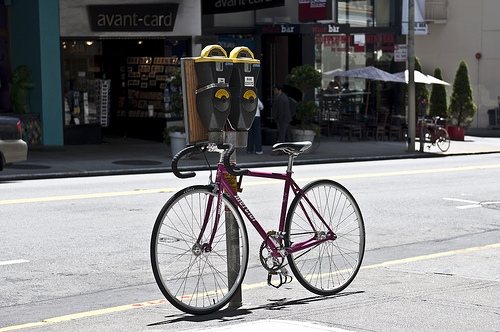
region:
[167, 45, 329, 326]
red bike near parking meter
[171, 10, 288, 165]
black and yellow parking meter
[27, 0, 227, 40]
black sign for avant cafe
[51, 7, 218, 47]
black sign with white lettering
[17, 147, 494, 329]
street with yellow lines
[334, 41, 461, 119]
white umbrellas in photograph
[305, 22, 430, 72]
red lettering on store front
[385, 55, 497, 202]
trees in photograph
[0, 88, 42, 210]
back end of vehicle in photo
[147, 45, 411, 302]
red bike tied to parking meter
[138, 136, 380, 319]
a purple bicycle on the sidewalk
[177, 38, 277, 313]
two parking meters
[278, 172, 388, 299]
a bicycle tire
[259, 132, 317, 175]
black bicycle seat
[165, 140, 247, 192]
black bicycle handle bars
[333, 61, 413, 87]
a large umbrella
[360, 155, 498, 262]
a paved road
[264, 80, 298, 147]
a person standing on the sidewalk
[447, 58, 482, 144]
a tree in a planter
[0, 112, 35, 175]
the bumper of a vehicle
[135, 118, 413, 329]
a red bike parked near a parking meter.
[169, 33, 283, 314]
two yellow parking meters.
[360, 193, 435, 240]
section of a public road.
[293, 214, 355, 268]
spokes within a bike wheel.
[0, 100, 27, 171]
back end of a motor vehicle.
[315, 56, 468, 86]
umbrellas covering seating area.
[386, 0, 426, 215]
large pole on the side of a street.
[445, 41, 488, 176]
a large pine tree near the side of a building.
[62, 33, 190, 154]
store front with sliding door.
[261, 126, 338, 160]
bike seat on the back of a bike.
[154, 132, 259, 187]
a bicycle with a curved handlebar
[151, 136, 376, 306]
a parked pink bicycle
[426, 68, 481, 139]
potted trees outside a bar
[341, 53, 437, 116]
white parasols on a bar's terrace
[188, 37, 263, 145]
two black and yellow parking meters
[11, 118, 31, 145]
the red taillight of a car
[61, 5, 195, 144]
the shop window of a card store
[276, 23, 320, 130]
the entrance to a bar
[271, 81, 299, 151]
a man wearing a blue suit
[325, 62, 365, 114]
a man sitting underneath a parasol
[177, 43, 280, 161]
A double parking meter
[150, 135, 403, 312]
A pink bike leaning against a parking meter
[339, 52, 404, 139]
An umbrella over a table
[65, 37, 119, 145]
A store window display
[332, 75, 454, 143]
Tables outside of a bar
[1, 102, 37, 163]
The tail end of a car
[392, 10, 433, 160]
The post of a street light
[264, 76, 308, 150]
A man wearing a suit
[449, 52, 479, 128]
A trimmed green tree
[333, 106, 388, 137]
Chairs around a table